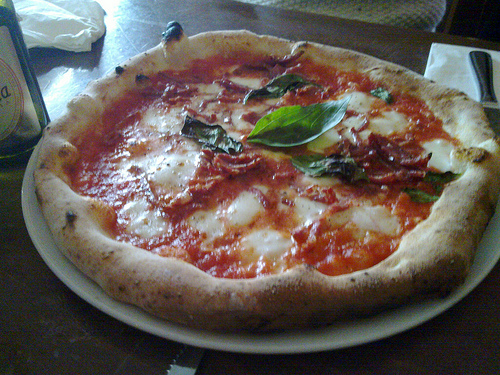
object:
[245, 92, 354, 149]
basil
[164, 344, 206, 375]
knife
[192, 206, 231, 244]
white mozzerella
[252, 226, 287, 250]
mozzerella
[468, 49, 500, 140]
knife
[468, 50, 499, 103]
handle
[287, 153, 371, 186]
basil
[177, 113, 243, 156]
basil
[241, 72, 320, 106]
basil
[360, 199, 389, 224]
mozzarella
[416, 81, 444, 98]
criust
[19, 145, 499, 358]
plate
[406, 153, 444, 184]
ground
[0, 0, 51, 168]
bottle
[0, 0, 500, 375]
table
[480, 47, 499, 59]
napkin corner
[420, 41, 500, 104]
napkin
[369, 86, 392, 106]
leaf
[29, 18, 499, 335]
pizza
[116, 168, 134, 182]
cheese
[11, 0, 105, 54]
napkin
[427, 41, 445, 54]
corner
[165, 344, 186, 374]
blade